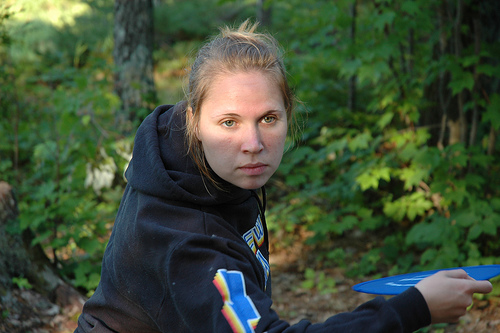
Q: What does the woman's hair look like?
A: Blonde.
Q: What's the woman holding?
A: A frisbee.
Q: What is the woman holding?
A: A frisbee.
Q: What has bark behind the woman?
A: Tree.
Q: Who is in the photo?
A: A lady.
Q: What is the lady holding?
A: A Frisbee.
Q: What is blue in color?
A: Frisbee.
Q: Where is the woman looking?
A: Past the camera.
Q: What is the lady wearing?
A: Sweatshirt.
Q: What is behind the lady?
A: Leaves.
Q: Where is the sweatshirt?
A: On the lady.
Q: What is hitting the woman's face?
A: Light.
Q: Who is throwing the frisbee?
A: Woman.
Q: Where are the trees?
A: Behind the woman.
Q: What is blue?
A: Frisbee.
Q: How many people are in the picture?
A: One.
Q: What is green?
A: Trees.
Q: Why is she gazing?
A: Talking aim on target.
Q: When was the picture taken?
A: Daytime.